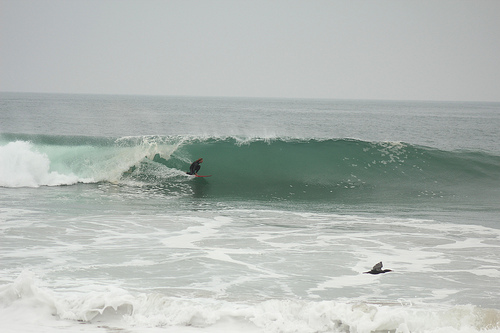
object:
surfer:
[186, 158, 205, 175]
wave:
[0, 133, 500, 191]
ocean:
[0, 94, 500, 333]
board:
[184, 174, 212, 178]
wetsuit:
[186, 161, 201, 175]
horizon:
[0, 90, 499, 103]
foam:
[0, 139, 94, 188]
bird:
[362, 261, 392, 275]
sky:
[0, 0, 500, 104]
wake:
[138, 158, 189, 185]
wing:
[373, 261, 383, 270]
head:
[384, 269, 393, 273]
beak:
[388, 269, 393, 272]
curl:
[122, 136, 183, 180]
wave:
[0, 278, 482, 333]